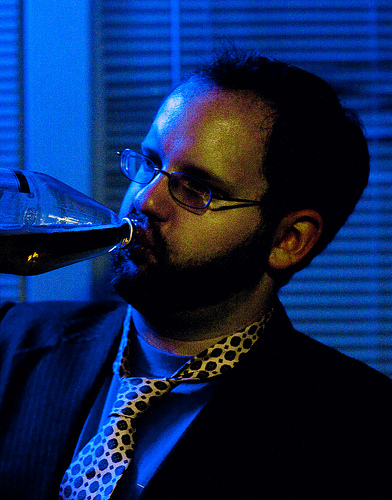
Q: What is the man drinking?
A: The man is drinking beer.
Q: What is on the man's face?
A: Glasses are on the mans face.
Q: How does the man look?
A: The man looks calm and relaxed.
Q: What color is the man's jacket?
A: The mans jacket is black.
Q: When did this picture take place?
A: It took place in the night time.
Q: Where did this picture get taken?
A: It probably was taken in a club or bar.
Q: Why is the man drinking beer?
A: So he can have a good time.